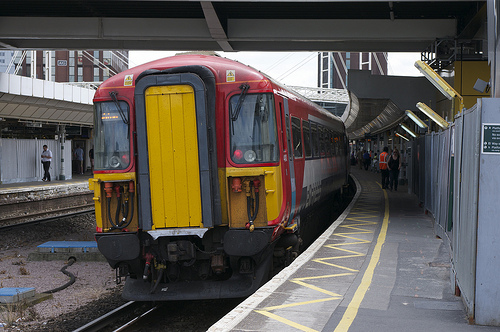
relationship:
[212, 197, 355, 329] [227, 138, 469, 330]
white line beside platform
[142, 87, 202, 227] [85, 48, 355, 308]
door in train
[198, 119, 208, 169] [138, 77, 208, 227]
lining on door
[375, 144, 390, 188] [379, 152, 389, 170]
man wearing orange vest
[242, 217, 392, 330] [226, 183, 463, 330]
lines are on platform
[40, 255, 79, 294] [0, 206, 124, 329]
hose on ground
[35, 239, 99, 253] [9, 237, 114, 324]
box on ground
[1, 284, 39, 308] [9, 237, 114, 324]
box on ground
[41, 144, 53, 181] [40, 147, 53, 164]
man wearing shirt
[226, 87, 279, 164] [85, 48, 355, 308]
window on train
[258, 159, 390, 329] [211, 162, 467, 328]
lines on platform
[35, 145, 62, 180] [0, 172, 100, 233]
man on platform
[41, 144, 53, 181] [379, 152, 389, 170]
man has orange vest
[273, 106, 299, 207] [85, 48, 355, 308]
doors on train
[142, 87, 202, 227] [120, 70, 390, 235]
door on train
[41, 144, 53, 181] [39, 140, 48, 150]
man has dark hair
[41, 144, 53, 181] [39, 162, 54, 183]
man wearing pants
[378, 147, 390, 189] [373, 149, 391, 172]
man wearing orange vest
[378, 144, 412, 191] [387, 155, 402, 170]
person wearing black shirt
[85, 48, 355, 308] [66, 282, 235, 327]
train on track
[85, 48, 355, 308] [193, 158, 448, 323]
train next to platform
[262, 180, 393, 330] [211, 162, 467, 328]
line on platform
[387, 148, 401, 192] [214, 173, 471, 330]
person on platform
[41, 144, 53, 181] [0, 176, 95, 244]
man on platform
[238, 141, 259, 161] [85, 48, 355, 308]
light on train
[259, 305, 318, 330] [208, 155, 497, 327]
line painted on ground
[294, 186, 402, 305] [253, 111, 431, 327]
line painted on ground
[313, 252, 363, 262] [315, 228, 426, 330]
line painted on ground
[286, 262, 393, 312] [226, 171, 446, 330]
yellow/painted line painted on ground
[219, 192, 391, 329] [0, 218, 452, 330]
line painted on ground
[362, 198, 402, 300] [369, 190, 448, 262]
line painted on ground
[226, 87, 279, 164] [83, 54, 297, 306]
window on back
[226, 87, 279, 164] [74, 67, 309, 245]
window on train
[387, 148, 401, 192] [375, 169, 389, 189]
person wearing pants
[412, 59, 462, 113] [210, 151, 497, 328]
light facing platform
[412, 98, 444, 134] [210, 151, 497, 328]
light facing platform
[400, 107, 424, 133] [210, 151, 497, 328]
light facing platform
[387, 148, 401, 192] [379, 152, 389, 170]
person wearing orange vest